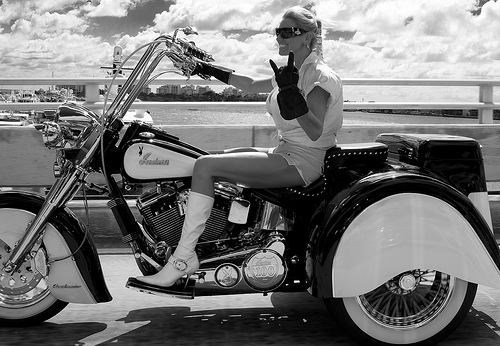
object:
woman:
[132, 4, 343, 291]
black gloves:
[266, 50, 311, 122]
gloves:
[266, 49, 310, 121]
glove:
[266, 52, 310, 122]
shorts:
[264, 136, 330, 188]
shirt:
[262, 49, 344, 150]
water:
[156, 104, 253, 124]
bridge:
[133, 4, 344, 289]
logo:
[134, 145, 171, 167]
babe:
[133, 3, 343, 290]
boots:
[133, 192, 214, 289]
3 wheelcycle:
[0, 25, 499, 345]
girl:
[135, 5, 343, 290]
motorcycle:
[1, 25, 498, 345]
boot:
[132, 188, 220, 290]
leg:
[133, 148, 311, 289]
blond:
[281, 3, 325, 63]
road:
[0, 241, 500, 343]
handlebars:
[140, 17, 219, 82]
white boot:
[133, 189, 212, 290]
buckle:
[171, 258, 189, 273]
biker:
[132, 4, 346, 291]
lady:
[132, 3, 345, 290]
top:
[261, 49, 343, 150]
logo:
[136, 146, 145, 158]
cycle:
[0, 26, 499, 345]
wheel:
[329, 264, 479, 344]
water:
[183, 110, 252, 120]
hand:
[266, 50, 311, 122]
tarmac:
[0, 238, 499, 341]